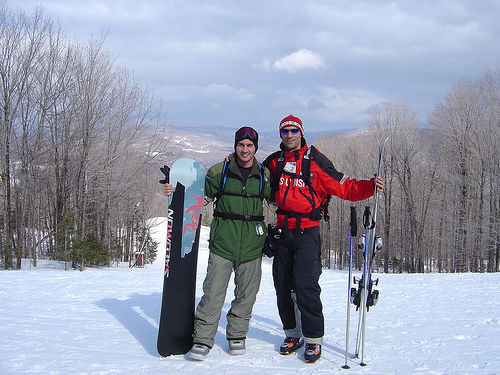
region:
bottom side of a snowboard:
[154, 152, 209, 362]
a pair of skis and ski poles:
[347, 126, 394, 373]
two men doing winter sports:
[151, 112, 395, 372]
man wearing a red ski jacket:
[256, 146, 380, 227]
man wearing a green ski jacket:
[201, 150, 273, 265]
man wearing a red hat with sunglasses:
[276, 112, 305, 139]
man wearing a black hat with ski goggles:
[231, 123, 262, 149]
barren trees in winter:
[2, 0, 497, 279]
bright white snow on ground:
[1, 213, 498, 373]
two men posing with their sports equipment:
[148, 106, 394, 371]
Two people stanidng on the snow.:
[166, 94, 365, 371]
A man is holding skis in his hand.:
[365, 105, 402, 357]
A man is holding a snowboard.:
[141, 127, 215, 354]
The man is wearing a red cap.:
[271, 107, 309, 132]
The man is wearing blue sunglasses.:
[279, 123, 309, 137]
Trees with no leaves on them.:
[15, 75, 152, 257]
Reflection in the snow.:
[109, 264, 169, 345]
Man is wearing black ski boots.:
[271, 329, 328, 366]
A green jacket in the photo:
[223, 176, 266, 266]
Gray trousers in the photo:
[190, 252, 262, 337]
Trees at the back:
[387, 105, 486, 251]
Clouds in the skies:
[192, 70, 289, 113]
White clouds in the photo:
[269, 36, 314, 76]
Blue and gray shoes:
[191, 341, 258, 364]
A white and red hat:
[277, 106, 309, 131]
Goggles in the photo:
[282, 124, 297, 136]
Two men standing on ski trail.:
[129, 111, 396, 373]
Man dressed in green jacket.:
[205, 156, 271, 263]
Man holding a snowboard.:
[148, 131, 214, 363]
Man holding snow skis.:
[351, 132, 396, 369]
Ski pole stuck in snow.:
[336, 203, 358, 373]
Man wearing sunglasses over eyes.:
[281, 121, 305, 138]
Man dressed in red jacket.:
[260, 145, 383, 235]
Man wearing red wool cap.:
[275, 112, 309, 132]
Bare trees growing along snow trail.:
[401, 104, 495, 273]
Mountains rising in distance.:
[140, 110, 233, 167]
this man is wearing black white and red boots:
[277, 335, 325, 364]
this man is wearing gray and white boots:
[187, 337, 250, 362]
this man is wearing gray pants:
[199, 249, 265, 346]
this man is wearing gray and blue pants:
[272, 232, 329, 337]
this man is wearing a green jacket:
[204, 151, 267, 262]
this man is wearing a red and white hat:
[278, 113, 303, 129]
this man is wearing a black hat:
[233, 125, 261, 141]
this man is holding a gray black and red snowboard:
[163, 150, 205, 356]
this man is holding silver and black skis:
[343, 130, 396, 372]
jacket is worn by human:
[266, 145, 382, 229]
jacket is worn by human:
[200, 153, 274, 262]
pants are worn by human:
[272, 224, 328, 346]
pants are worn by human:
[189, 250, 272, 348]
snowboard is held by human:
[155, 157, 207, 359]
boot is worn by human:
[189, 342, 211, 363]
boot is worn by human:
[227, 334, 249, 356]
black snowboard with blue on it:
[144, 137, 215, 368]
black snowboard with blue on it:
[138, 140, 229, 365]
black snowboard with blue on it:
[139, 137, 224, 363]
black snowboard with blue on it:
[138, 145, 220, 356]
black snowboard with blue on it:
[134, 140, 217, 372]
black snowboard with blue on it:
[135, 146, 228, 362]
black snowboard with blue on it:
[136, 148, 228, 368]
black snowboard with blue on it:
[135, 142, 222, 366]